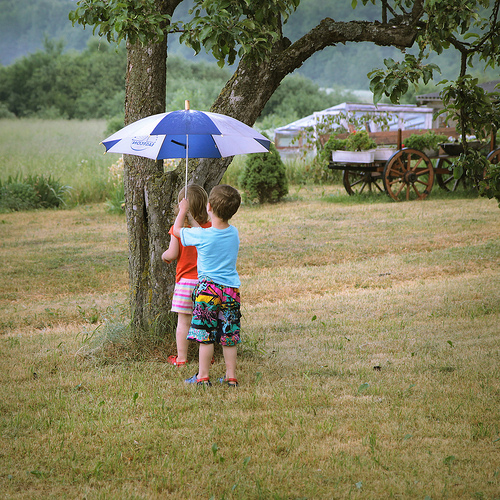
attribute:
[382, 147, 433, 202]
wheel — round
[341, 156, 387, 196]
wheel — round